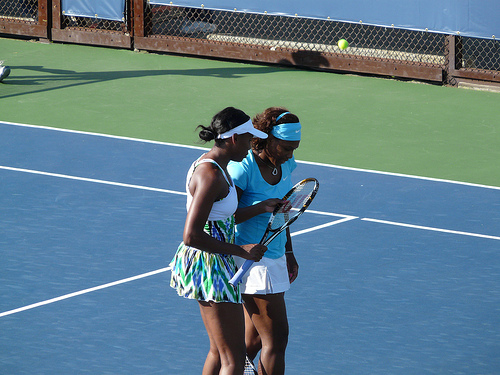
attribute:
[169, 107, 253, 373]
tennis player — talking, female, playing tennis, african american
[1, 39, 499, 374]
court — blue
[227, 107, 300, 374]
tennis player — listening, female, playing tennis, african american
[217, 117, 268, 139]
visor — white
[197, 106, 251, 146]
hair — pulled back, black, held up, in bun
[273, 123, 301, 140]
band — thick, light blue, nike, blue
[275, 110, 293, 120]
band — thick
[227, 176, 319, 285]
racket — wilson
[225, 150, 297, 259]
shirt — blue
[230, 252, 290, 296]
skirt — white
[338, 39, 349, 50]
ball — yellow, in air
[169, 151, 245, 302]
tennis dress — short-length, colorful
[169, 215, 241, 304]
designs — blue, green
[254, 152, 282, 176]
necklace — silver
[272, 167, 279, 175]
pendant — shiny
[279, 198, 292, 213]
fingers — curled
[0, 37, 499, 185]
out-of-bounds — green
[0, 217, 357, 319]
singles line — white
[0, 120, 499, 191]
line — white